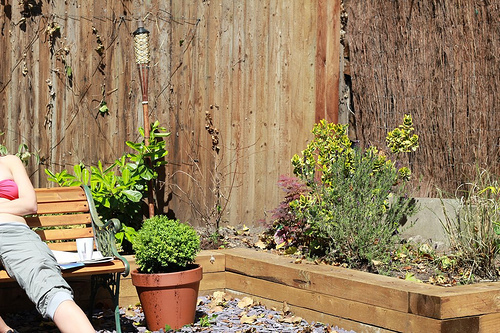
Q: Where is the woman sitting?
A: On the bench.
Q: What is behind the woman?
A: A fence.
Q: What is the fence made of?
A: Wood.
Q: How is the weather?
A: Sunny and warm.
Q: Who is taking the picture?
A: A friend.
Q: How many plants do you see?
A: 4.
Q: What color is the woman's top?
A: Pink.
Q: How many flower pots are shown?
A: 1.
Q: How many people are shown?
A: 1.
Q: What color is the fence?
A: Brown.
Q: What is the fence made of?
A: Wood.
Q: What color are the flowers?
A: Yellow.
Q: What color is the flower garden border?
A: Brown.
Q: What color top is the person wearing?
A: Pink.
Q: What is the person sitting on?
A: Bench.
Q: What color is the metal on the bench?
A: Green.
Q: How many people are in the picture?
A: 1.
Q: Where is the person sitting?
A: On a bench.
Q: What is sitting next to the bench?
A: A pot.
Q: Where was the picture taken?
A: In a garden.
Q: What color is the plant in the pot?
A: Green.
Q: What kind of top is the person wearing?
A: Bikini top.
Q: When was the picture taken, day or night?
A: During the day.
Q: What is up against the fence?
A: A lantern.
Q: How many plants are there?
A: 5.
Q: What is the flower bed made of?
A: Wood.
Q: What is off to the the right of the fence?
A: A tree.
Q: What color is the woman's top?
A: Pink.